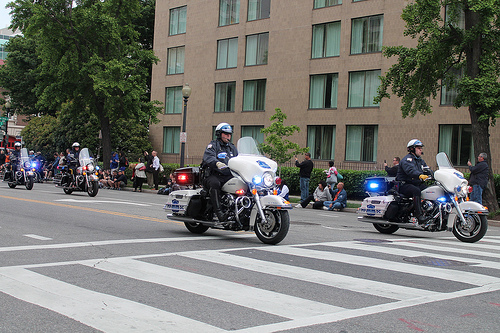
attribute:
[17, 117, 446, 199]
cops — arranged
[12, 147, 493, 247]
bikes — white, lit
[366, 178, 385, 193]
light — on, blue, red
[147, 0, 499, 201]
building — beige, brown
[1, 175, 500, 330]
street — lined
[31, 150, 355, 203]
people — dressed, gathered, looking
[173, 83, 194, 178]
lamp — off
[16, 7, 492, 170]
trees — tall